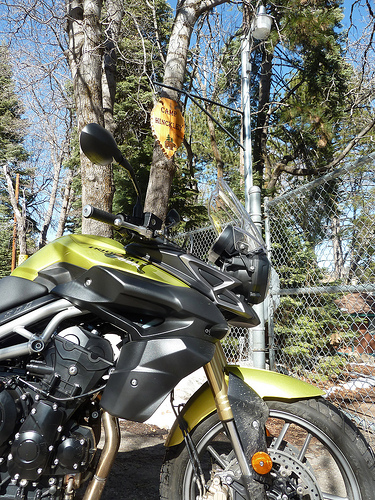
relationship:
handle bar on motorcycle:
[80, 203, 190, 255] [0, 122, 375, 500]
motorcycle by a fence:
[155, 142, 374, 450] [170, 146, 372, 361]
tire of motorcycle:
[156, 364, 373, 497] [148, 367, 363, 496]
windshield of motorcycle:
[200, 180, 272, 252] [1, 122, 374, 499]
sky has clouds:
[1, 1, 373, 247] [2, 1, 359, 112]